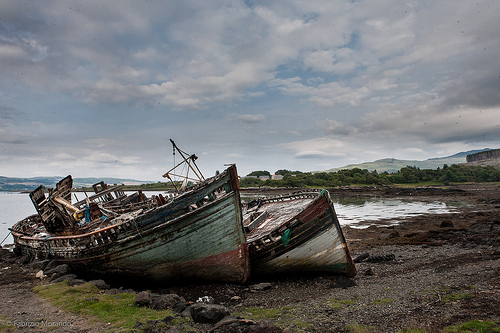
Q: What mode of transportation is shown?
A: Boats.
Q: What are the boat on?
A: Ground.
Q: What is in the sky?
A: Clouds.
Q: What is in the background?
A: Hills.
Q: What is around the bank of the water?
A: Trees.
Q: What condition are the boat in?
A: Old and needing repairs.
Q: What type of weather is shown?
A: Cloudy.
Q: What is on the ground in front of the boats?
A: Gravel.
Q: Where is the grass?
A: Left side of the boat.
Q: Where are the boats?
A: Beach.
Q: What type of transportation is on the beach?
A: Boats.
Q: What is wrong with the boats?
A: Broken.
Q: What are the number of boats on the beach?
A: 2.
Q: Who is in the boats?
A: Nobody.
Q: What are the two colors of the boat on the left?
A: Red and green.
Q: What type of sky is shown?
A: Cloudy.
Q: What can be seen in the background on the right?
A: Mountain.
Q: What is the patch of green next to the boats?
A: Grass.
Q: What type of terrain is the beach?
A: Rocky.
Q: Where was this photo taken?
A: Sea side.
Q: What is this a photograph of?
A: Shipwreck.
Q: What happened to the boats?
A: They shipwrecked.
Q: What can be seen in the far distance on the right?
A: Mountains.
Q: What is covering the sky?
A: White clouds.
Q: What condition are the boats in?
A: Shipwrecked.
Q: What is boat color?
A: Green and red.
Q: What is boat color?
A: White and red.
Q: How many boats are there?
A: Two.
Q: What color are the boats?
A: Blue and white.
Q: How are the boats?
A: Old.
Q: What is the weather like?
A: Cloudy.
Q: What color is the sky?
A: Blue.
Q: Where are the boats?
A: On the shore.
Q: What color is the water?
A: Blue.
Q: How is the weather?
A: Mild.